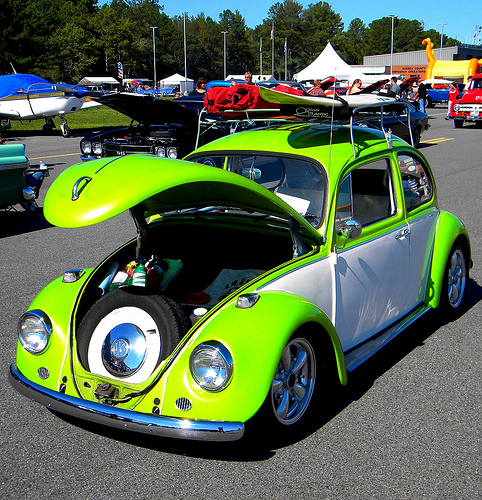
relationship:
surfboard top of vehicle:
[256, 84, 396, 109] [8, 120, 474, 446]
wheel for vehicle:
[78, 282, 181, 388] [8, 120, 474, 446]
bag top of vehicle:
[201, 84, 228, 111] [8, 120, 474, 446]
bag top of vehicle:
[228, 80, 302, 110] [8, 120, 474, 446]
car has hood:
[81, 84, 266, 159] [90, 92, 197, 125]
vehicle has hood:
[8, 120, 474, 446] [41, 151, 325, 239]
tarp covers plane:
[0, 71, 89, 98] [1, 59, 90, 137]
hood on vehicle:
[41, 151, 325, 239] [8, 120, 474, 446]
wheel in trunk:
[78, 282, 181, 388] [75, 235, 291, 392]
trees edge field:
[2, 0, 457, 82] [2, 98, 176, 128]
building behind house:
[361, 45, 481, 64] [416, 38, 481, 87]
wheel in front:
[78, 282, 181, 388] [6, 155, 323, 457]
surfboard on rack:
[256, 84, 396, 109] [193, 110, 418, 151]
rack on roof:
[193, 110, 418, 151] [178, 126, 413, 161]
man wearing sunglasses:
[242, 67, 255, 84] [243, 74, 255, 79]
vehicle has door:
[8, 120, 474, 446] [332, 222, 427, 351]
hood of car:
[90, 92, 197, 125] [81, 84, 266, 159]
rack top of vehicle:
[193, 110, 418, 151] [8, 120, 474, 446]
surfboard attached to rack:
[256, 84, 396, 109] [193, 110, 418, 151]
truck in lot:
[448, 70, 480, 125] [0, 111, 481, 498]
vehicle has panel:
[8, 120, 474, 446] [256, 258, 335, 324]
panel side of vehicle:
[256, 258, 335, 324] [8, 120, 474, 446]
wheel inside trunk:
[78, 282, 181, 388] [75, 235, 291, 392]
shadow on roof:
[286, 125, 392, 150] [178, 126, 413, 161]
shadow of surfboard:
[286, 125, 392, 150] [256, 84, 396, 109]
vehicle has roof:
[8, 120, 474, 446] [178, 126, 413, 161]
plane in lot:
[1, 59, 90, 137] [0, 111, 481, 498]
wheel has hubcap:
[78, 282, 181, 388] [101, 321, 149, 379]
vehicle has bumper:
[8, 120, 474, 446] [6, 362, 244, 446]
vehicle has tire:
[8, 120, 474, 446] [259, 331, 328, 442]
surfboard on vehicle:
[256, 84, 396, 109] [8, 120, 474, 446]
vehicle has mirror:
[8, 120, 474, 446] [239, 164, 263, 180]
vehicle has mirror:
[8, 120, 474, 446] [339, 219, 366, 239]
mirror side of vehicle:
[339, 219, 366, 239] [8, 120, 474, 446]